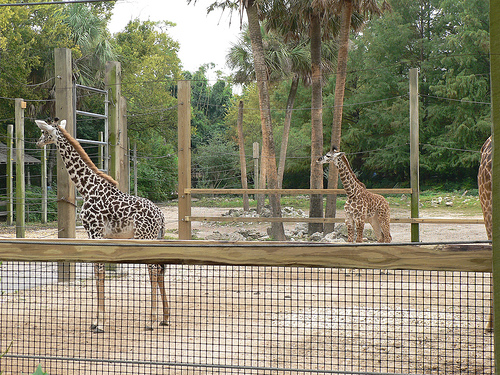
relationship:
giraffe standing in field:
[273, 147, 390, 238] [7, 193, 482, 371]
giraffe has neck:
[34, 116, 168, 333] [330, 161, 364, 201]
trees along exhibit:
[241, 11, 383, 185] [19, 54, 493, 352]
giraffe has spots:
[26, 113, 191, 345] [84, 193, 138, 235]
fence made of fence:
[1, 260, 491, 373] [1, 258, 500, 372]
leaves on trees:
[10, 1, 485, 194] [3, 1, 498, 194]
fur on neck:
[56, 125, 119, 194] [52, 127, 104, 197]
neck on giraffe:
[52, 127, 104, 197] [34, 116, 168, 333]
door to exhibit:
[69, 80, 110, 233] [5, 3, 484, 368]